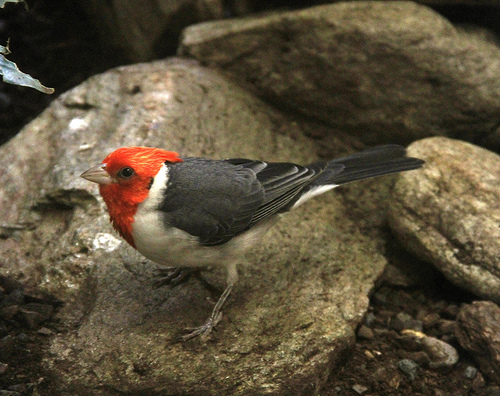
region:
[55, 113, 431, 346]
this is a bird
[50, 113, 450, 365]
this is a small bird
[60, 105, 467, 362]
the bird is on a rock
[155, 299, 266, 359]
the talons of a bird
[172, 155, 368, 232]
grey feathers on a bird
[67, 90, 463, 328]
the bird's head is red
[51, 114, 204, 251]
the bird has a bright red head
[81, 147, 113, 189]
this is the beak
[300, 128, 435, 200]
the long tail feathers of a bird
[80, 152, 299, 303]
bird staring in the open air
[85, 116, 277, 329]
bird is standing on the rock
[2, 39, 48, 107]
a tree leaf in the picture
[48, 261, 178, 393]
the rocks are grey in color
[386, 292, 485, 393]
floor has some pieces of the rocks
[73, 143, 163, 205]
head of the bird is red in color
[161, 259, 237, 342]
legs are black in color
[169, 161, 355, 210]
back and tail feather are black in color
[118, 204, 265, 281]
inner feather are white in color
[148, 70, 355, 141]
these are some stones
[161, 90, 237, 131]
the stone is big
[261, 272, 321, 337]
the stone is grey in color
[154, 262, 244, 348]
these are the feet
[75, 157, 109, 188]
this is a beak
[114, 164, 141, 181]
this is an eye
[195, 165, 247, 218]
the feathers are grey in color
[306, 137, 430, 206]
this is a tail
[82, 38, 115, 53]
the area is dark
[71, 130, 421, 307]
this is a bird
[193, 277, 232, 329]
this is the leg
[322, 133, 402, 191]
this is the tail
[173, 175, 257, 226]
this is the wing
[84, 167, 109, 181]
this is the beak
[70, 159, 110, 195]
the beak is short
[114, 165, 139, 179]
this is a eye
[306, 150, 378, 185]
the tail is black in color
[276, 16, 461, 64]
this is a rock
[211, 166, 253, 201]
the wing is black in color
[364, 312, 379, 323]
A rock on the ground.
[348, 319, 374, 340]
A rock on the ground.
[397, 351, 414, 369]
A rock on the ground.